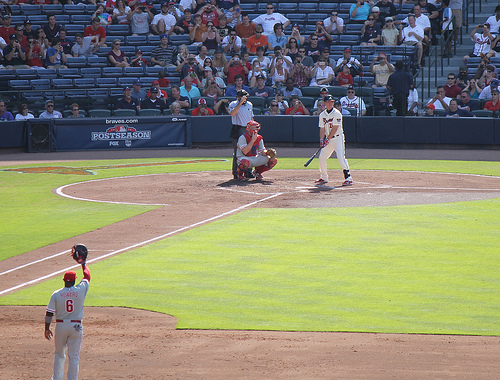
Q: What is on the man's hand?
A: Glove.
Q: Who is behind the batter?
A: Catcher.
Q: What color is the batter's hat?
A: Black.